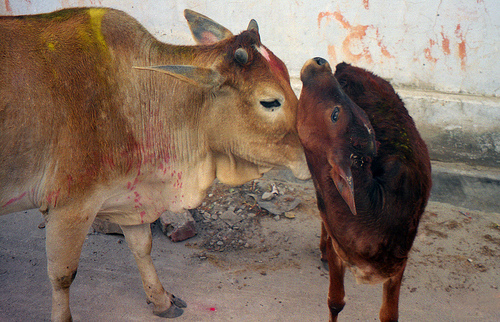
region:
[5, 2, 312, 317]
Caw is light brown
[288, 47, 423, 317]
Calf is dark brown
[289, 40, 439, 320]
Calf has head up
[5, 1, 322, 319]
Cow sniff on calf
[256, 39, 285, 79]
Cow has red stain on front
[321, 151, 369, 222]
Big pointy ear of calf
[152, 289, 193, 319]
Hoof of calf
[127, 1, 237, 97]
Pointy ears of cow are back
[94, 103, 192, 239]
Cow has red stains on side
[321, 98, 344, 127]
Black eye of calf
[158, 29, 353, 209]
two animals kissing each other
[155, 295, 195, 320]
the animal's paw is black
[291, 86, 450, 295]
This animal is a brown color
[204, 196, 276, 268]
there are stones on the ground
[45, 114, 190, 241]
there are red spots on the animal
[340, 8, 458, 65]
there is graffitti on the wall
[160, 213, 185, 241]
there is a rock on the ground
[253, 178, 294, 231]
there are assorted objects on the ground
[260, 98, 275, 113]
animal's eye is black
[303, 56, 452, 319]
this animal is shorter.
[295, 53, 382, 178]
brown calf looking up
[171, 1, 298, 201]
light brown adult cow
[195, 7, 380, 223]
adult cow and baby cow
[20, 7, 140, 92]
yellow paint on cow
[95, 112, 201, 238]
red paint on cow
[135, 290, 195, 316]
cow hoof on ground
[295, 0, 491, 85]
graffiti on wall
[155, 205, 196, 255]
brick on ground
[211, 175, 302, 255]
rocks or crushed bricks on ground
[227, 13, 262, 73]
horns on light brown cow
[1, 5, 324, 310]
a large cow nuzzling a smaller one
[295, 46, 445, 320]
a small dark cow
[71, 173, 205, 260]
two broken red bricks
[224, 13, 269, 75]
two stubby horns on a large cow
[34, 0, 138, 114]
yellow paint on a cows back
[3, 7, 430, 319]
two very long eared cows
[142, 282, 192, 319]
the small black hoof of a cow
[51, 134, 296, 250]
some loose neck skin on a cow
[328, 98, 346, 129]
a small dark cow's eye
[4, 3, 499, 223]
a white cement wall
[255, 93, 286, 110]
the eye of a cow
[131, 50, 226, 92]
the ear of a cow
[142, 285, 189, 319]
the hoof of a gow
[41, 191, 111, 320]
the leg of a cow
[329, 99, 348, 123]
the eye of a cow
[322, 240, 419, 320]
the legs of a cow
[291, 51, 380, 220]
the head of a cow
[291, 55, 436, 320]
a dark brown cow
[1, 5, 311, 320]
a light tan cow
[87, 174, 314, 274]
gravel on the ground